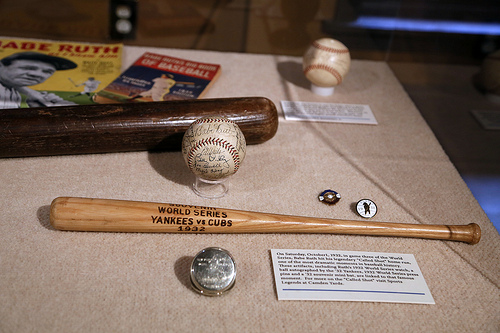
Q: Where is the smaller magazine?
A: Beside the larger magazine.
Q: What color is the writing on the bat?
A: Black.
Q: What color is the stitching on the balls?
A: Red.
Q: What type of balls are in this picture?
A: Baseballs.